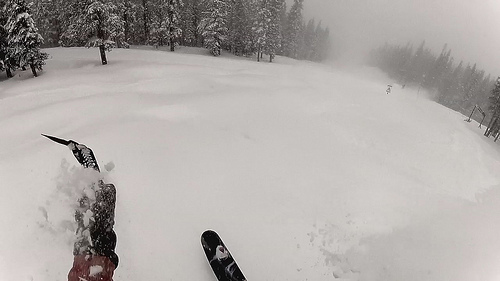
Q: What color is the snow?
A: White.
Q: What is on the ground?
A: Snow.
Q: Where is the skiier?
A: On the mountain.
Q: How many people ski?
A: One.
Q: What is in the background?
A: Trees.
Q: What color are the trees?
A: Green.